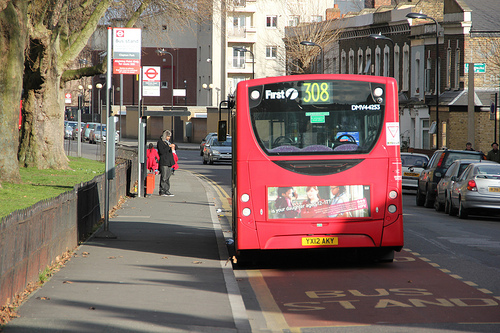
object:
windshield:
[252, 110, 378, 151]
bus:
[227, 73, 399, 256]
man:
[156, 128, 179, 194]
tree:
[16, 1, 111, 170]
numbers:
[296, 82, 330, 104]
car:
[410, 148, 494, 205]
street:
[171, 145, 499, 333]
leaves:
[45, 257, 75, 267]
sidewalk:
[9, 166, 251, 332]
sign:
[140, 65, 162, 96]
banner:
[265, 186, 374, 221]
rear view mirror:
[214, 120, 227, 143]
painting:
[281, 285, 486, 311]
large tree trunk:
[21, 30, 71, 168]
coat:
[155, 137, 177, 167]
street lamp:
[403, 13, 443, 150]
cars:
[443, 160, 496, 218]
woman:
[145, 141, 158, 176]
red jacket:
[145, 147, 156, 164]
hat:
[162, 130, 176, 137]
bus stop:
[129, 60, 160, 196]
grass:
[0, 153, 106, 218]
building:
[77, 2, 499, 154]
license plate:
[298, 233, 338, 248]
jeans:
[158, 165, 173, 192]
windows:
[232, 57, 240, 67]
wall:
[2, 160, 131, 321]